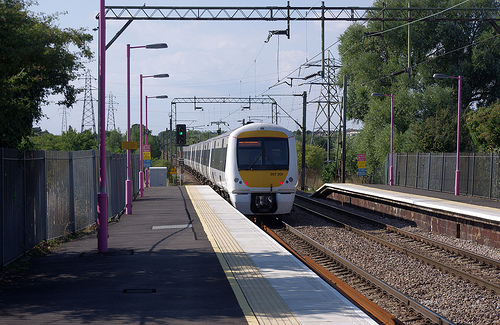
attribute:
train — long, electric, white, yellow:
[178, 117, 305, 224]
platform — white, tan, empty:
[181, 181, 385, 324]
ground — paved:
[1, 178, 246, 324]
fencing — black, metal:
[0, 147, 157, 270]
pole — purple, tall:
[429, 68, 468, 197]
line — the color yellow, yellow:
[181, 181, 261, 323]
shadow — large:
[1, 244, 342, 322]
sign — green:
[172, 121, 188, 148]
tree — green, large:
[1, 1, 103, 147]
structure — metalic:
[147, 165, 170, 185]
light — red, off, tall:
[368, 85, 403, 187]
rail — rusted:
[259, 223, 405, 324]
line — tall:
[79, 62, 102, 141]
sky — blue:
[10, 2, 383, 135]